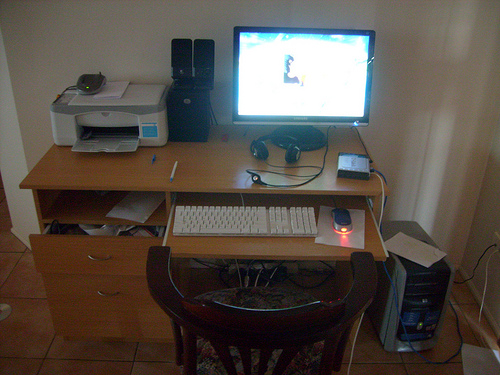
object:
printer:
[48, 71, 172, 154]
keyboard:
[171, 204, 318, 238]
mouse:
[331, 207, 355, 236]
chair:
[146, 244, 380, 374]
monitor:
[231, 23, 372, 127]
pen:
[169, 160, 177, 183]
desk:
[19, 120, 391, 347]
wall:
[10, 15, 135, 79]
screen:
[235, 29, 361, 118]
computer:
[375, 253, 470, 366]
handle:
[87, 246, 121, 265]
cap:
[152, 155, 158, 164]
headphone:
[249, 133, 302, 168]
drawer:
[29, 195, 162, 284]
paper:
[105, 188, 166, 224]